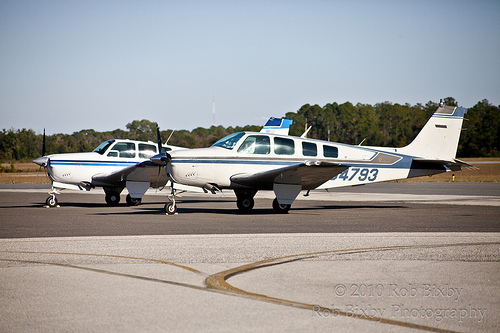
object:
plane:
[150, 98, 480, 215]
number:
[331, 168, 378, 181]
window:
[235, 135, 272, 156]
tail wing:
[399, 98, 470, 158]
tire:
[126, 194, 142, 206]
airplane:
[33, 116, 368, 209]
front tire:
[45, 195, 58, 207]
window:
[106, 142, 136, 158]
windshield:
[92, 140, 114, 156]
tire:
[105, 192, 122, 205]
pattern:
[204, 241, 499, 332]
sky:
[0, 1, 499, 126]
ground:
[0, 183, 499, 332]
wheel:
[163, 201, 177, 214]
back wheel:
[236, 195, 254, 209]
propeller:
[150, 124, 170, 193]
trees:
[0, 96, 499, 163]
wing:
[91, 159, 172, 189]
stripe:
[169, 156, 372, 163]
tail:
[437, 154, 480, 174]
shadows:
[85, 203, 410, 215]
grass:
[1, 156, 49, 184]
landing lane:
[0, 181, 499, 236]